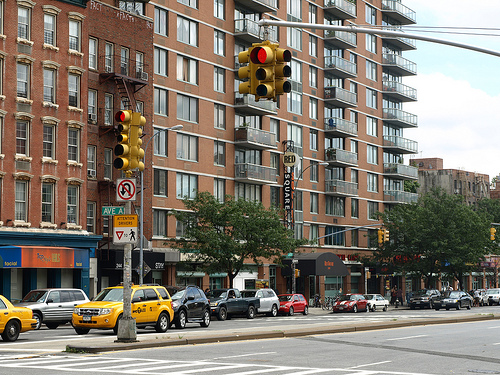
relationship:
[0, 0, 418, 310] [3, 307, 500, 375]
building by street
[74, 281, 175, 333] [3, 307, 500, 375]
taxi on street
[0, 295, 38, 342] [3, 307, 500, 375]
taxi on street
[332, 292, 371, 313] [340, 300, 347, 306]
car has white stripes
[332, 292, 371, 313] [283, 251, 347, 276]
car parked near awning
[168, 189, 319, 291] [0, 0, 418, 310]
tree in front of building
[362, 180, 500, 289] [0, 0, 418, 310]
tree in front of building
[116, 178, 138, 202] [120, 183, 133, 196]
sign with no u-turn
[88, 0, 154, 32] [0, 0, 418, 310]
graffiti on building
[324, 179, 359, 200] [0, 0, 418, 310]
balcony on building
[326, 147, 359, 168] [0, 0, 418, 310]
balcony on building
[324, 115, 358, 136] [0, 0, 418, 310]
balcony on building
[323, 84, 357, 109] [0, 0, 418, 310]
balcony on building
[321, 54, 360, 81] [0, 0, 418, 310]
balcony on building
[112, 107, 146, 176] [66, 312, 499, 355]
traffic light on median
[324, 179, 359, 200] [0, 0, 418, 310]
balcony outside building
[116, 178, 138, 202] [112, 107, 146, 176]
sign below traffic light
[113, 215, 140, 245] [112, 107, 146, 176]
sign below traffic light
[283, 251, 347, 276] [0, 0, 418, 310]
awning in front of building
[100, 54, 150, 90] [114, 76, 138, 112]
balcony above ladder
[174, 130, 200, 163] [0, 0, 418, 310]
window on building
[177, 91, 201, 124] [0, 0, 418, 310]
window on building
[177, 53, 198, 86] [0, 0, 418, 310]
window on building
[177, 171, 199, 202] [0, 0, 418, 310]
window on building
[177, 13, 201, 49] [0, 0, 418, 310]
window on building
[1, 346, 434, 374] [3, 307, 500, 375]
crosswalk on street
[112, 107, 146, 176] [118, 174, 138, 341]
traffic light on pole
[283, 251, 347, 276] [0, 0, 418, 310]
awning on building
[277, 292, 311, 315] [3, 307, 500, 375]
car parked beside street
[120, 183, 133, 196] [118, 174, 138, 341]
no u-turn on pole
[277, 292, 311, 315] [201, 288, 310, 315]
car in line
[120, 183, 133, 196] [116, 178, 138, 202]
no u-turn on sign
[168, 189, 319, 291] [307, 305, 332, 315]
tree on sidewalk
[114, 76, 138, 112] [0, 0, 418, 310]
ladder on building